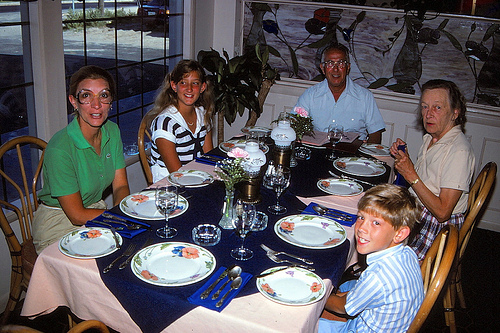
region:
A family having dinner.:
[64, 37, 443, 303]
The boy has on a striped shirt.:
[322, 246, 424, 329]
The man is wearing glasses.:
[305, 36, 356, 87]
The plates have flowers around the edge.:
[138, 229, 231, 309]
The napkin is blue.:
[199, 254, 246, 307]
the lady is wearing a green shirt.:
[49, 115, 129, 211]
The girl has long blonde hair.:
[156, 53, 224, 145]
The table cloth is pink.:
[37, 227, 327, 332]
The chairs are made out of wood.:
[6, 118, 64, 308]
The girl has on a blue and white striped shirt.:
[153, 93, 238, 175]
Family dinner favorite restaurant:
[73, 49, 438, 321]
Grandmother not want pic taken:
[408, 79, 485, 212]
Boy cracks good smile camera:
[342, 179, 433, 319]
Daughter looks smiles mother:
[137, 54, 217, 167]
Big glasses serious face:
[47, 71, 127, 226]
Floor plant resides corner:
[198, 39, 267, 133]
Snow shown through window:
[62, 1, 184, 56]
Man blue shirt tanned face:
[301, 38, 386, 134]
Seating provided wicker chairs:
[4, 119, 46, 321]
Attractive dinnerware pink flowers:
[162, 112, 340, 312]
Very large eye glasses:
[74, 85, 113, 106]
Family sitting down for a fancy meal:
[45, 22, 480, 308]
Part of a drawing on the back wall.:
[247, 2, 443, 50]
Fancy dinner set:
[113, 229, 248, 315]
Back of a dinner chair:
[421, 228, 467, 290]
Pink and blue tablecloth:
[87, 277, 170, 328]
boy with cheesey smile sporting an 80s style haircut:
[354, 179, 421, 261]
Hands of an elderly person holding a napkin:
[391, 139, 418, 189]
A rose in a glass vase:
[213, 147, 248, 229]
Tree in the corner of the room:
[199, 44, 261, 141]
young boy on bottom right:
[350, 181, 417, 331]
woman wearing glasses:
[55, 62, 120, 239]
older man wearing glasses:
[311, 40, 381, 151]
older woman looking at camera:
[402, 75, 467, 230]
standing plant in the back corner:
[200, 35, 277, 155]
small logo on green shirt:
[103, 152, 115, 161]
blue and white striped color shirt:
[351, 250, 418, 331]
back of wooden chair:
[420, 222, 459, 304]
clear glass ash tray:
[192, 224, 220, 246]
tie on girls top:
[182, 130, 207, 160]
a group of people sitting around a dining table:
[23, 40, 466, 321]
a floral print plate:
[130, 235, 217, 290]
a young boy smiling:
[330, 169, 439, 331]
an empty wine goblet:
[150, 177, 185, 239]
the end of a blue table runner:
[86, 260, 191, 327]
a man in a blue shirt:
[291, 43, 376, 141]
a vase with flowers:
[215, 151, 242, 226]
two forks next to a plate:
[260, 234, 312, 273]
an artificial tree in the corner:
[196, 41, 265, 133]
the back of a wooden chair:
[0, 124, 38, 258]